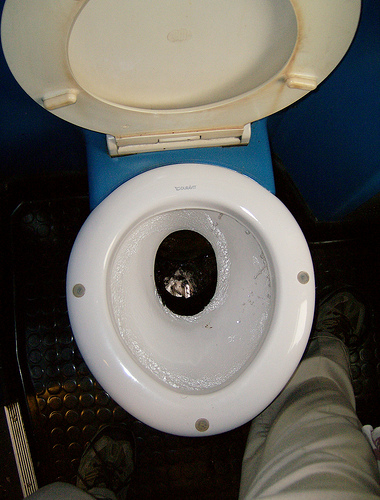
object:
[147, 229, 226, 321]
base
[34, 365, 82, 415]
metal floor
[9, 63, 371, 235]
wall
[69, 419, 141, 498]
shoe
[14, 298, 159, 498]
mat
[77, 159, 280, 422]
toilet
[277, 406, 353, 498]
khaki pants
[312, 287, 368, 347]
shoe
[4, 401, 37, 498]
door hinge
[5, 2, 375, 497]
bathroom stall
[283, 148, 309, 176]
ground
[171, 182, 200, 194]
name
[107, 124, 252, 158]
hinged base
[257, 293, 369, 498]
leg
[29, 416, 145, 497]
leg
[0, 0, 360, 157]
lid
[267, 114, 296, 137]
ground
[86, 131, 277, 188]
support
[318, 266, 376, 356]
boot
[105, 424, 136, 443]
tip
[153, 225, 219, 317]
black hole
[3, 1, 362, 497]
bathroom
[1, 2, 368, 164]
toilet seat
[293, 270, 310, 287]
dots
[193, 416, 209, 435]
dots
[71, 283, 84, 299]
dots